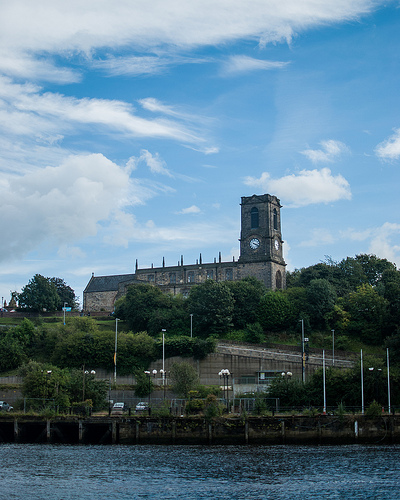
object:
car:
[111, 402, 127, 414]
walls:
[238, 260, 272, 290]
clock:
[249, 237, 261, 250]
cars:
[135, 401, 150, 412]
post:
[162, 329, 166, 386]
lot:
[0, 394, 391, 413]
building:
[82, 193, 287, 319]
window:
[225, 268, 234, 281]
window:
[206, 270, 213, 280]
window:
[187, 271, 195, 283]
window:
[169, 272, 177, 284]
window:
[147, 274, 155, 282]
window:
[181, 288, 191, 301]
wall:
[2, 346, 393, 404]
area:
[0, 402, 400, 416]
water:
[2, 442, 399, 498]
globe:
[227, 372, 230, 376]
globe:
[224, 368, 228, 373]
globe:
[221, 369, 225, 373]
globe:
[218, 372, 222, 376]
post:
[227, 377, 229, 415]